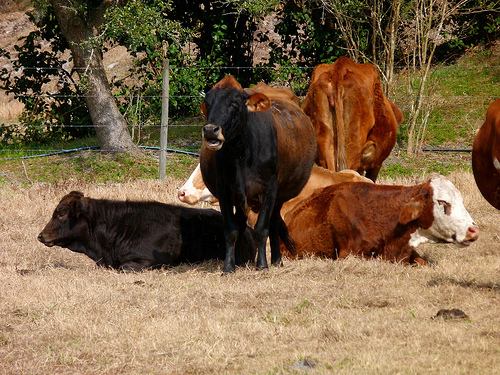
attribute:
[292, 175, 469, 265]
cow — one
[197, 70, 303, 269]
cow — one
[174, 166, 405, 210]
cow — one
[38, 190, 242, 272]
cow — one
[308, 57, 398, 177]
cow — one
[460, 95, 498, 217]
cow — one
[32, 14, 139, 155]
tree — one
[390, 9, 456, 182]
tree — one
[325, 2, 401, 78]
tree — one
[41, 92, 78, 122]
leaf — one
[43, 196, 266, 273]
cow — one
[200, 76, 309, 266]
cow — one